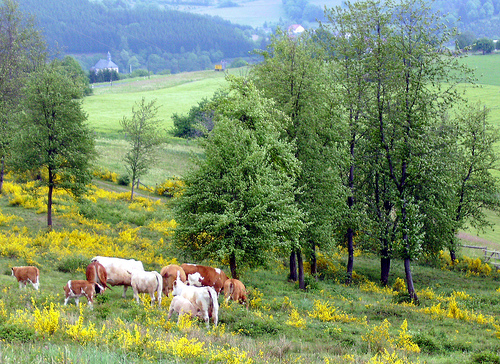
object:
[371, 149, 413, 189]
wall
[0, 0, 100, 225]
tree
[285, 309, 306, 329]
flower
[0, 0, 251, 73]
hills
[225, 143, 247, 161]
leaves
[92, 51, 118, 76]
house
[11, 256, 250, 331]
herd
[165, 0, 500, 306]
tree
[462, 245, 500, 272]
fence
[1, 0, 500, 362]
field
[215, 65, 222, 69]
yellow vehicle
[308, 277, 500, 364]
flowers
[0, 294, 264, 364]
flowers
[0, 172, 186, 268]
flowers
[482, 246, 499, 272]
gate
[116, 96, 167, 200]
tree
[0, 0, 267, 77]
tree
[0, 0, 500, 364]
hillside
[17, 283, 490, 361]
ground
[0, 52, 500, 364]
grass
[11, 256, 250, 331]
cow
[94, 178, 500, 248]
road